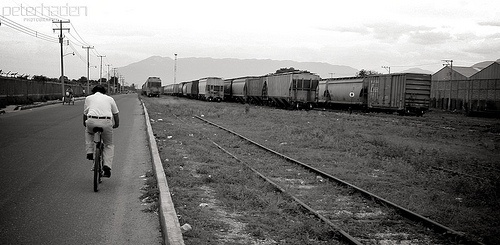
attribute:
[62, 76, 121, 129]
man — riding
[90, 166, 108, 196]
bicycle — three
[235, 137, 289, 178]
tracks — empty, iron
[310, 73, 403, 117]
train — traveling, abandoned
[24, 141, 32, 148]
road — asphalt, cement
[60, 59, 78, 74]
pole — telephone\, telephone pole, left of man, utility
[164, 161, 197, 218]
grass — growing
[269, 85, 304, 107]
engine — distant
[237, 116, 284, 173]
rail — stone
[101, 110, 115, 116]
shirt — light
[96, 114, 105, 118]
belt — dark, black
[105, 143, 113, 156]
pants — dark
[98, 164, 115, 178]
shoes — dark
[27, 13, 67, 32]
wires — black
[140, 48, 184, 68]
mountain — far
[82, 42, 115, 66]
lights — line